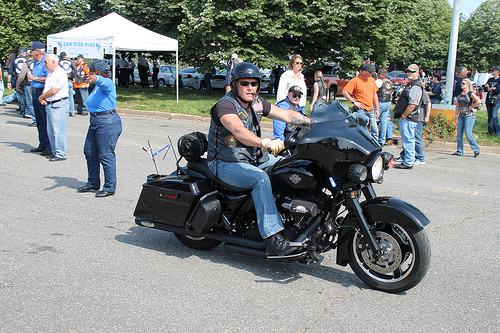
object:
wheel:
[348, 216, 432, 293]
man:
[206, 62, 317, 259]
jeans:
[207, 154, 285, 240]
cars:
[129, 64, 430, 101]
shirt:
[342, 76, 379, 112]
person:
[392, 63, 424, 171]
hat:
[26, 41, 46, 50]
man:
[341, 64, 381, 142]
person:
[74, 59, 122, 198]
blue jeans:
[82, 109, 121, 193]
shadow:
[113, 225, 407, 296]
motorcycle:
[131, 98, 433, 293]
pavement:
[0, 103, 498, 331]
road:
[5, 102, 498, 331]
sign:
[46, 35, 116, 60]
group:
[112, 51, 161, 89]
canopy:
[46, 11, 181, 104]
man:
[38, 53, 72, 161]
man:
[26, 41, 54, 155]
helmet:
[229, 62, 263, 94]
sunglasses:
[236, 81, 258, 87]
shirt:
[276, 70, 309, 107]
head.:
[29, 41, 45, 58]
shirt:
[85, 75, 117, 113]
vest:
[206, 90, 270, 163]